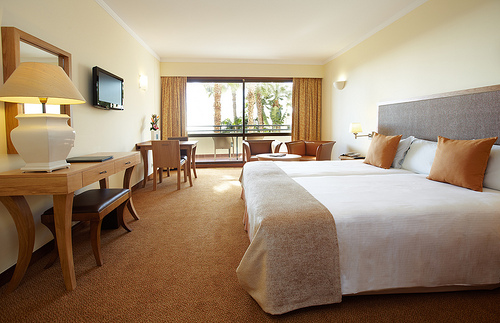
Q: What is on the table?
A: A lamp.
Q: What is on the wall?
A: A television.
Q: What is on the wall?
A: A mirror.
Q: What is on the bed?
A: Pillows.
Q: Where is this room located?
A: In a hotel.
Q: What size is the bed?
A: A huge king size.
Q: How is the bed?
A: It is made.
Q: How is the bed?
A: It is made.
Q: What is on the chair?
A: It's empty.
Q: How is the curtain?
A: It is drawn.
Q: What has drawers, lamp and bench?
A: A wooden desk.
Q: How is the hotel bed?
A: Large and made.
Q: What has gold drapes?
A: Large picture windows.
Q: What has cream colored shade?
A: A white table lamp.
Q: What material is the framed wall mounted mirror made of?
A: Wood.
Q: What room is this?
A: Bedroom.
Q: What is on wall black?
A: Tv.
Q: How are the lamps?
A: On.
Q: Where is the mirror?
A: Wall.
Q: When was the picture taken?
A: Daytime.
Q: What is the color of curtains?
A: Gold.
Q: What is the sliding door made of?
A: Glass.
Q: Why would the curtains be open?
A: To view.